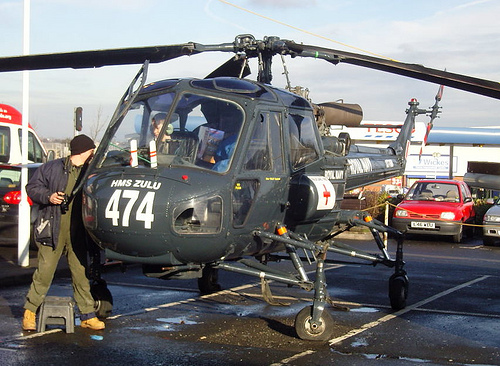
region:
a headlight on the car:
[428, 199, 462, 229]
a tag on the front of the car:
[410, 213, 437, 243]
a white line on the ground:
[349, 301, 389, 361]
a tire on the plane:
[280, 296, 340, 358]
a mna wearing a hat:
[63, 125, 98, 162]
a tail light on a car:
[4, 180, 29, 218]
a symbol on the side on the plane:
[310, 170, 336, 217]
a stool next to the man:
[32, 284, 89, 356]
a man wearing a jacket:
[28, 145, 76, 258]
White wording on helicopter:
[100, 174, 165, 237]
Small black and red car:
[382, 163, 479, 248]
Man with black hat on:
[65, 131, 100, 166]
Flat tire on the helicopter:
[290, 296, 337, 352]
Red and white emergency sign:
[305, 163, 337, 217]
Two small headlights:
[388, 205, 459, 225]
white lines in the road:
[0, 266, 495, 363]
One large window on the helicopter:
[91, 83, 250, 180]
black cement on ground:
[156, 304, 209, 334]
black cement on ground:
[427, 302, 467, 360]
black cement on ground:
[424, 252, 466, 301]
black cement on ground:
[132, 288, 165, 311]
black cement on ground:
[22, 339, 70, 361]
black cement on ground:
[104, 263, 160, 303]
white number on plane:
[99, 187, 194, 232]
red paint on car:
[408, 183, 495, 254]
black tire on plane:
[281, 289, 351, 360]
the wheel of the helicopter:
[274, 289, 343, 351]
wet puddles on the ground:
[136, 287, 274, 352]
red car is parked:
[400, 174, 481, 235]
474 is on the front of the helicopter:
[96, 175, 168, 240]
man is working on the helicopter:
[27, 131, 122, 338]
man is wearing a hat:
[67, 130, 95, 158]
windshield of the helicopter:
[117, 90, 231, 175]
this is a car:
[396, 173, 476, 230]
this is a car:
[477, 192, 498, 239]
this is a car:
[0, 108, 49, 223]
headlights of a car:
[432, 208, 454, 219]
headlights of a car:
[384, 208, 412, 221]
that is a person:
[21, 133, 101, 328]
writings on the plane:
[106, 178, 169, 229]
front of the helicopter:
[38, 75, 284, 290]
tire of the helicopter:
[256, 283, 355, 361]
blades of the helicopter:
[5, 24, 484, 111]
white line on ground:
[419, 267, 482, 317]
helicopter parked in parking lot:
[0, 25, 495, 316]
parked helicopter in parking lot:
[1, 25, 496, 345]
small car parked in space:
[391, 171, 471, 253]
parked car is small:
[391, 172, 473, 246]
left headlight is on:
[439, 207, 455, 223]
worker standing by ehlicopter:
[22, 130, 110, 335]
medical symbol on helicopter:
[306, 169, 338, 217]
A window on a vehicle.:
[167, 85, 236, 175]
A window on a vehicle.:
[122, 85, 175, 174]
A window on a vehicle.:
[166, 201, 233, 238]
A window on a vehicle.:
[241, 105, 296, 172]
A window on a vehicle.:
[282, 106, 319, 171]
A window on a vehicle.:
[410, 178, 460, 203]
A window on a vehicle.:
[457, 182, 469, 199]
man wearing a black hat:
[64, 132, 94, 162]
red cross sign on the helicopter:
[308, 166, 348, 213]